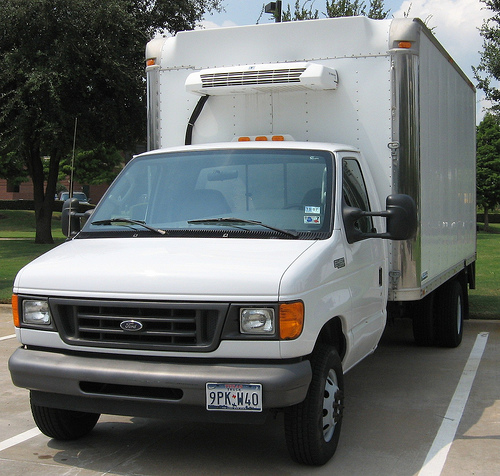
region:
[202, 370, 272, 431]
a texas license plate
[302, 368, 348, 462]
black tire with white rim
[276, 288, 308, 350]
small orange van light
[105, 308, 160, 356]
blua nad silver ford emblem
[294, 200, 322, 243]
stickers on a windshield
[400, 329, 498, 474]
white stripe painted on road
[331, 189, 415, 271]
black side mirror on truck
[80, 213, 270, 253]
two black wind shield wipers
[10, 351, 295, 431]
front bumper of a car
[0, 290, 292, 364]
head lights on front of of vehicle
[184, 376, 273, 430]
The license is TX.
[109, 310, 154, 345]
The truck is a ford.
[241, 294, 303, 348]
The light is white.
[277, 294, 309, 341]
The light is orange.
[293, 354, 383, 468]
The tire is black.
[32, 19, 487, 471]
The truck is white.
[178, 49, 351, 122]
The truck has a vent.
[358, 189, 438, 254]
The mirror is black.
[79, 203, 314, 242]
The windhield wipers are on the truck.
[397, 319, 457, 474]
The line is white.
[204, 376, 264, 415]
The license plate on the front of the truck.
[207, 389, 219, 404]
The number 9 on the license plate.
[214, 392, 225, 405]
The letter P on the license plate.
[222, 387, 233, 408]
The letter K on the license plate.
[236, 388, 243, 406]
The letter W on the license plate.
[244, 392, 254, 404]
The number 4 on the license plate.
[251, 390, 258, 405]
The number 0 on the license plate.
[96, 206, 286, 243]
The windshield wipers on the truck.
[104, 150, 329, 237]
The front windshield window on the truck.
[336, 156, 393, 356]
The driver side door.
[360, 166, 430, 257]
black side mirror on vehicle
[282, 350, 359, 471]
black tire and white rim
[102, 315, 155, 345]
a blue and silver ford emblem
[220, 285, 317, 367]
hgead lights on a vehicle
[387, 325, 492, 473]
painted white stripe on cement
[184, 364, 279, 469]
a texas license plate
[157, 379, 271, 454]
blue white and red licnse plate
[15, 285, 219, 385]
front grill of a vehicle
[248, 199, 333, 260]
two white stickers on vehicle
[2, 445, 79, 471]
stain on the cement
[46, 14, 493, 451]
A large white truck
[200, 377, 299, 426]
license plate on the truck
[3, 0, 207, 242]
A large tree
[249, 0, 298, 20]
The top of a street light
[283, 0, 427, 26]
The top of a tree behind the truck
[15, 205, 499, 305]
a grassy landscape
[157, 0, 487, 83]
A blue, cloudy sky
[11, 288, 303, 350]
The headlights on the truck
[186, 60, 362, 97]
the vent for the trailer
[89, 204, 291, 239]
windshield wipers on the truck